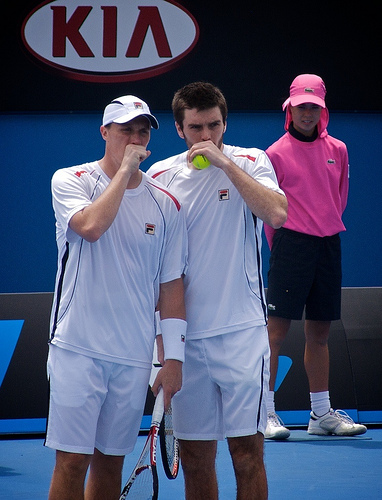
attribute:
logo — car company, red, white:
[22, 2, 203, 83]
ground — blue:
[2, 432, 380, 500]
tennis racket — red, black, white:
[118, 388, 166, 500]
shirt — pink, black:
[261, 130, 353, 247]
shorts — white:
[44, 342, 150, 463]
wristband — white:
[159, 314, 191, 361]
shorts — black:
[265, 229, 346, 321]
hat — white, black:
[95, 94, 163, 129]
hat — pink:
[277, 74, 331, 141]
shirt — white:
[46, 165, 190, 366]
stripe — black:
[50, 244, 72, 337]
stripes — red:
[64, 167, 185, 214]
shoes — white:
[259, 415, 367, 439]